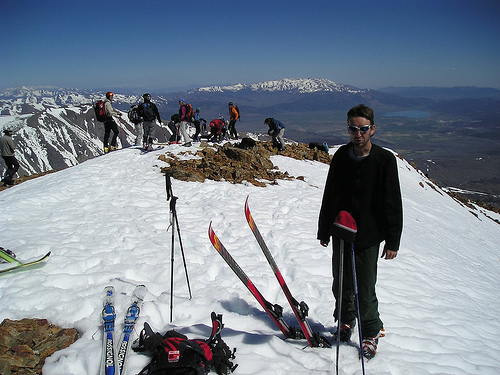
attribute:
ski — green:
[3, 250, 19, 264]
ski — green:
[2, 256, 48, 277]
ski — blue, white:
[94, 281, 118, 372]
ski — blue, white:
[128, 291, 148, 369]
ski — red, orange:
[208, 217, 248, 291]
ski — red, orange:
[244, 194, 307, 273]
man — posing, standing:
[322, 106, 404, 360]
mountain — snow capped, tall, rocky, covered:
[208, 80, 375, 105]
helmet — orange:
[106, 91, 115, 98]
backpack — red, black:
[91, 96, 107, 124]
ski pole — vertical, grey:
[167, 199, 177, 321]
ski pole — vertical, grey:
[174, 179, 192, 294]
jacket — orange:
[227, 107, 241, 119]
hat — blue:
[178, 98, 186, 104]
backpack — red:
[187, 102, 195, 122]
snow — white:
[26, 156, 494, 367]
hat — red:
[335, 212, 360, 246]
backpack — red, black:
[145, 312, 234, 369]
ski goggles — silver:
[348, 122, 374, 134]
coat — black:
[329, 143, 396, 242]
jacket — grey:
[104, 100, 117, 116]